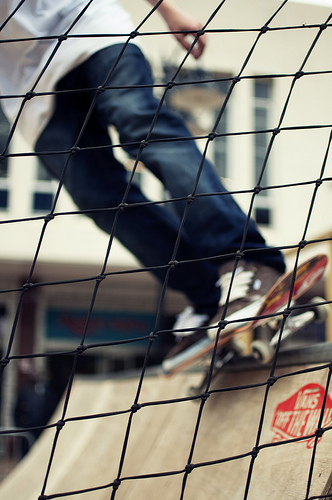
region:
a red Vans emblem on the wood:
[269, 380, 330, 449]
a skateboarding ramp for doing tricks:
[0, 342, 331, 498]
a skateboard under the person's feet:
[152, 253, 331, 404]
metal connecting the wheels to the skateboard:
[251, 300, 317, 343]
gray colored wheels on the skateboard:
[185, 293, 329, 403]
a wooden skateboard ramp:
[0, 342, 331, 499]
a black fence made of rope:
[0, 0, 331, 498]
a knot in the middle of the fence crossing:
[198, 390, 211, 403]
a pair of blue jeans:
[33, 41, 289, 310]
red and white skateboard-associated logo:
[270, 383, 330, 449]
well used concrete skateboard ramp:
[2, 372, 330, 498]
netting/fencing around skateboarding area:
[0, 0, 330, 498]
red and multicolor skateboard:
[160, 253, 328, 402]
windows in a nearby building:
[3, 58, 279, 232]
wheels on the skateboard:
[187, 296, 331, 403]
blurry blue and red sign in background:
[43, 302, 331, 345]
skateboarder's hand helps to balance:
[164, 14, 206, 60]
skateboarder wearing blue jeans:
[30, 43, 287, 313]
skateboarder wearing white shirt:
[0, 0, 141, 150]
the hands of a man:
[164, 6, 224, 65]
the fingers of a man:
[157, 12, 225, 63]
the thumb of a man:
[172, 18, 194, 71]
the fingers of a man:
[178, 5, 233, 76]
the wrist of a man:
[150, 0, 191, 55]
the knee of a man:
[112, 83, 210, 161]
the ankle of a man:
[194, 199, 280, 271]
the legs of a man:
[79, 54, 318, 383]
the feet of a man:
[155, 236, 323, 391]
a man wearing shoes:
[148, 226, 308, 385]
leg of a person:
[88, 153, 171, 293]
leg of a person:
[157, 130, 252, 240]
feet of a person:
[144, 280, 223, 380]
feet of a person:
[193, 246, 301, 353]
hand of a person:
[135, 0, 226, 66]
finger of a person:
[171, 18, 226, 56]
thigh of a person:
[76, 9, 156, 141]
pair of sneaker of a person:
[155, 240, 290, 361]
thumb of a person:
[167, 34, 199, 65]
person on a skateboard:
[65, 43, 323, 376]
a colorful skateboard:
[156, 247, 330, 401]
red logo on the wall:
[254, 380, 330, 437]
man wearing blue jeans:
[24, 53, 273, 293]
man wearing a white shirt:
[1, 1, 155, 132]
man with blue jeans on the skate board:
[22, 45, 269, 275]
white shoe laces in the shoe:
[169, 306, 204, 343]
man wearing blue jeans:
[26, 40, 268, 276]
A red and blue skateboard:
[156, 253, 327, 401]